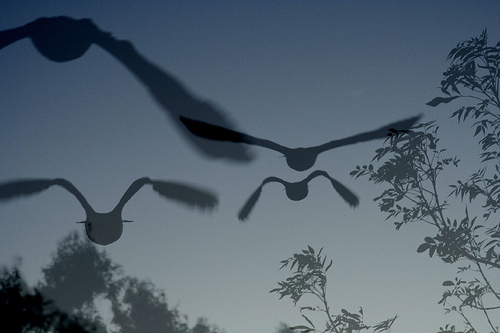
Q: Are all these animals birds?
A: Yes, all the animals are birds.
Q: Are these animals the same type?
A: Yes, all the animals are birds.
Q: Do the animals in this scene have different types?
A: No, all the animals are birds.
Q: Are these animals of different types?
A: No, all the animals are birds.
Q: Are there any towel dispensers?
A: No, there are no towel dispensers.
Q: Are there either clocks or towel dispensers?
A: No, there are no towel dispensers or clocks.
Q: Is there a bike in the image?
A: No, there are no bikes.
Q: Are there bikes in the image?
A: No, there are no bikes.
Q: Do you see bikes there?
A: No, there are no bikes.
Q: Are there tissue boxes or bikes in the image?
A: No, there are no bikes or tissue boxes.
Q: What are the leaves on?
A: The leaves are on the branch.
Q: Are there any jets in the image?
A: No, there are no jets.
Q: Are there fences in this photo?
A: No, there are no fences.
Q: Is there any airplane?
A: No, there are no airplanes.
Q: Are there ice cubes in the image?
A: No, there are no ice cubes.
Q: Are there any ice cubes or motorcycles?
A: No, there are no ice cubes or motorcycles.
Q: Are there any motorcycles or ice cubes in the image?
A: No, there are no ice cubes or motorcycles.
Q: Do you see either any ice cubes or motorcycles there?
A: No, there are no ice cubes or motorcycles.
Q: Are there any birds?
A: Yes, there is a bird.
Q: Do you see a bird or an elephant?
A: Yes, there is a bird.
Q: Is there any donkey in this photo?
A: No, there are no donkeys.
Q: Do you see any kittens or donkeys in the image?
A: No, there are no donkeys or kittens.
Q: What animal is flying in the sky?
A: The bird is flying in the sky.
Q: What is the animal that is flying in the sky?
A: The animal is a bird.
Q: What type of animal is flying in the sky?
A: The animal is a bird.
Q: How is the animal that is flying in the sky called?
A: The animal is a bird.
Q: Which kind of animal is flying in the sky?
A: The animal is a bird.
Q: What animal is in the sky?
A: The bird is in the sky.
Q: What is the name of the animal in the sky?
A: The animal is a bird.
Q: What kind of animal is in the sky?
A: The animal is a bird.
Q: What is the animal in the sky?
A: The animal is a bird.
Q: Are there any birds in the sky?
A: Yes, there is a bird in the sky.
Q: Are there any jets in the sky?
A: No, there is a bird in the sky.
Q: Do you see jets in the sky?
A: No, there is a bird in the sky.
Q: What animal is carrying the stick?
A: The bird is carrying the stick.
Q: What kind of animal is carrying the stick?
A: The animal is a bird.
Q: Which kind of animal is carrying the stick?
A: The animal is a bird.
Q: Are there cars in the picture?
A: No, there are no cars.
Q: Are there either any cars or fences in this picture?
A: No, there are no cars or fences.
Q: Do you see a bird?
A: Yes, there is a bird.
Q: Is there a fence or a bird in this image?
A: Yes, there is a bird.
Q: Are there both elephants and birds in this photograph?
A: No, there is a bird but no elephants.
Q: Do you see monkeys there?
A: No, there are no monkeys.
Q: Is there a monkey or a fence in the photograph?
A: No, there are no monkeys or fences.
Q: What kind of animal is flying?
A: The animal is a bird.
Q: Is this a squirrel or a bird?
A: This is a bird.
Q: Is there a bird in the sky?
A: Yes, there is a bird in the sky.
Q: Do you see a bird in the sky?
A: Yes, there is a bird in the sky.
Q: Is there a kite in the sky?
A: No, there is a bird in the sky.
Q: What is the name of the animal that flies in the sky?
A: The animal is a bird.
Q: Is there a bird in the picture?
A: Yes, there is a bird.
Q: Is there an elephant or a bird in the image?
A: Yes, there is a bird.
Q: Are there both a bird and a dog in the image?
A: No, there is a bird but no dogs.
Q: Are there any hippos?
A: No, there are no hippos.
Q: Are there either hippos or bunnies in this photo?
A: No, there are no hippos or bunnies.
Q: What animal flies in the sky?
A: The bird flies in the sky.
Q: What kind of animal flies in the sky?
A: The animal is a bird.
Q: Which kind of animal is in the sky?
A: The animal is a bird.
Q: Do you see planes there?
A: No, there are no planes.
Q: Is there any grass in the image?
A: Yes, there is grass.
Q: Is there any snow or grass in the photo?
A: Yes, there is grass.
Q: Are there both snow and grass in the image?
A: No, there is grass but no snow.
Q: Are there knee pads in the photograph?
A: No, there are no knee pads.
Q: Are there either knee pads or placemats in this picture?
A: No, there are no knee pads or placemats.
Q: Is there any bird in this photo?
A: Yes, there is a bird.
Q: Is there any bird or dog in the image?
A: Yes, there is a bird.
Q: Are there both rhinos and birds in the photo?
A: No, there is a bird but no rhinos.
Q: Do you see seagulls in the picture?
A: No, there are no seagulls.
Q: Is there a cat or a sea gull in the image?
A: No, there are no seagulls or cats.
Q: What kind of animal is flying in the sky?
A: The animal is a bird.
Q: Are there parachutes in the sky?
A: No, there is a bird in the sky.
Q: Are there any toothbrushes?
A: No, there are no toothbrushes.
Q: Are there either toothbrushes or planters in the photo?
A: No, there are no toothbrushes or planters.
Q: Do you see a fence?
A: No, there are no fences.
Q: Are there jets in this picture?
A: No, there are no jets.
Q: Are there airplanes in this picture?
A: No, there are no airplanes.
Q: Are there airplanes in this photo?
A: No, there are no airplanes.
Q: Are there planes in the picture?
A: No, there are no planes.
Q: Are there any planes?
A: No, there are no planes.